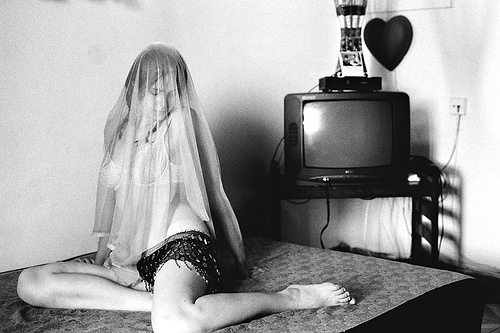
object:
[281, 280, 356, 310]
foot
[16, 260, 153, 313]
leg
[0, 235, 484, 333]
bed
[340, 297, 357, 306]
toe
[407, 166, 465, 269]
shadow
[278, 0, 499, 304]
wall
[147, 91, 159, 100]
eyes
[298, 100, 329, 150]
light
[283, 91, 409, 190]
tv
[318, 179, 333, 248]
cord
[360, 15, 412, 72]
heart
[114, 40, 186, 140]
hair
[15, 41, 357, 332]
girl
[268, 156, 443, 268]
stand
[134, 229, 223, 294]
shorts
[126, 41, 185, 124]
head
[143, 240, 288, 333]
leg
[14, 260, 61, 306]
knee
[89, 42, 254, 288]
veil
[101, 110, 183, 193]
bra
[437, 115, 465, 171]
cord